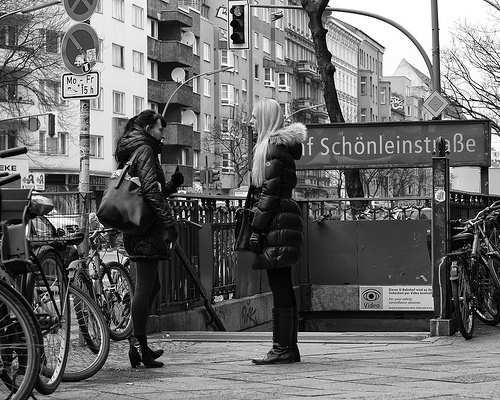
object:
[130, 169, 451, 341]
subway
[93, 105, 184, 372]
woman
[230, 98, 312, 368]
woman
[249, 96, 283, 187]
hair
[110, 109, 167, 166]
hair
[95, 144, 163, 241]
purse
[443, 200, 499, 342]
bicycle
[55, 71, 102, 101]
sign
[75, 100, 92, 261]
post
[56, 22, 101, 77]
sign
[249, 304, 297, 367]
boot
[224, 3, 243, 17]
signal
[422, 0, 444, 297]
pole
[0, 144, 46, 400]
bikes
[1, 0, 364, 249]
buildings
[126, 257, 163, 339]
leggings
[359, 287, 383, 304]
eye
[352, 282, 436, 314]
sign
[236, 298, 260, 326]
graffitti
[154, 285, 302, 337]
concrete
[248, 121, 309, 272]
jacket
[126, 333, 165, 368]
boot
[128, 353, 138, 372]
heel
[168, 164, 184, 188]
glove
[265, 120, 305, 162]
hood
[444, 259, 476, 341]
wheel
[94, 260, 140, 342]
wheel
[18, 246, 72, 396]
wheel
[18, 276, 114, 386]
wheel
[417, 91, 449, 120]
sign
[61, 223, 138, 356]
bike